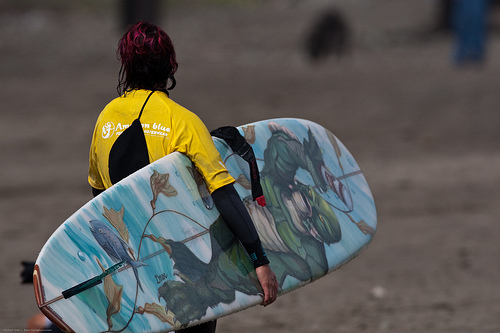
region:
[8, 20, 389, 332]
person walking on sand with surboard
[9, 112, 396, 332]
blue and white surfboard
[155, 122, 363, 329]
green monster on face of surfboard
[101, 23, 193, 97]
head of wet hair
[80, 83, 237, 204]
yellow short sleeve shirt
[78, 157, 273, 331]
black wetsuit under yellow t-shirt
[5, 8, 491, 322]
tan sand on ground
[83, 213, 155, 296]
grey fish on surfboard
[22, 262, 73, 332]
brown edge of surfboard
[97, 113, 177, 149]
white print on the back of yellow t-shirt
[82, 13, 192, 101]
a woman with pink streaked hair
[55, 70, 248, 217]
a woman wearing a yellow jersey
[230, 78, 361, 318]
a surfboard painted with a sea monster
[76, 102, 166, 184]
a black backpack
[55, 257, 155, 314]
the fin of a surfboard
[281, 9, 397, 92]
a dog just out of focus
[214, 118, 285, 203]
the wrist strap of a surfboard leash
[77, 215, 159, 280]
a picture of a fish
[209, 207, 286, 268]
the sleeve of a wetsuit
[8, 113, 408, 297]
surf board in person's arms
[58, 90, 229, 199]
shirt on the woman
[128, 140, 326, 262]
image on the board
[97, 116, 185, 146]
graphic on the shirt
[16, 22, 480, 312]
ground with dirt and rocks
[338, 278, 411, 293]
rock on the ground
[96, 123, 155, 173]
bag on woman's back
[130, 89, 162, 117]
strap to the bag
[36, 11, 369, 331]
woman walking down beach with surf board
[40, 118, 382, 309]
creature of the black lagoon airbrushed on surfboard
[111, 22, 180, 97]
woman has red and black dyed hair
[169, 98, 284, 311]
right arm gripping surfboard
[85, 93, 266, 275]
yellow shirt over a black wetsuit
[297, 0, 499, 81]
blurred figures in the foreground on beach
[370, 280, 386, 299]
piece of litter on the sand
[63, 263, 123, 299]
fin on underside of surfboard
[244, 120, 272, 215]
safety strap of surfboard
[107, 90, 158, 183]
black bag on the woman's back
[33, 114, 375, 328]
a large surf board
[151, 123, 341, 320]
a character on the board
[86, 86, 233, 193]
a yellow tee shirt with white writing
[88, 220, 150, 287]
a fish drawing on the board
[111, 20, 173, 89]
woman has pink hair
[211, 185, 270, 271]
a black long sleeve shirt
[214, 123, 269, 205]
a piece of clothing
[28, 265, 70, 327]
back end of the board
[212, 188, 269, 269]
the wetsuit is black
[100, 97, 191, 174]
the shirt is golden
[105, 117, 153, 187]
the sack is black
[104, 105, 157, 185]
sack is on the back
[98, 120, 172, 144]
words are on the shirt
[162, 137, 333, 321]
the creature is green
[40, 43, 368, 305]
a person holding the surfboard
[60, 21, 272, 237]
a person wearin ga shirt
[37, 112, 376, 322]
a large surfboard being held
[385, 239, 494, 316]
sand on the ground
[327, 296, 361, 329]
sand on the ground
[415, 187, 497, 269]
sand on the ground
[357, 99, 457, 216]
sand on the ground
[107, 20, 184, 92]
maroon hair on a woman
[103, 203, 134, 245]
leaf on a surfboard